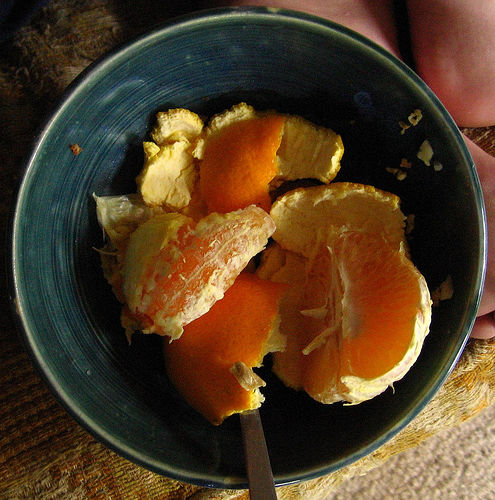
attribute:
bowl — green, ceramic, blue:
[13, 9, 481, 487]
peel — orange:
[189, 324, 251, 396]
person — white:
[411, 2, 494, 334]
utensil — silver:
[238, 408, 281, 499]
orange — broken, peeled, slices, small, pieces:
[104, 199, 437, 410]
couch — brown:
[17, 421, 488, 500]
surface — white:
[400, 439, 494, 498]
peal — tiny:
[144, 103, 207, 144]